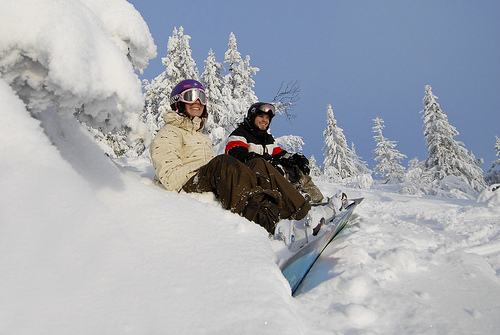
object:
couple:
[149, 80, 347, 253]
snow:
[1, 191, 497, 333]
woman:
[150, 79, 340, 251]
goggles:
[180, 88, 208, 106]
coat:
[150, 111, 215, 190]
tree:
[141, 26, 204, 131]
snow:
[0, 0, 159, 178]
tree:
[419, 83, 488, 190]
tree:
[320, 103, 374, 182]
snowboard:
[278, 197, 363, 296]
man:
[225, 103, 347, 213]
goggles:
[259, 103, 275, 115]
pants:
[176, 153, 311, 233]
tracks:
[344, 200, 500, 244]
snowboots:
[310, 197, 344, 219]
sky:
[126, 0, 498, 170]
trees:
[219, 31, 257, 136]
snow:
[144, 25, 498, 200]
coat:
[225, 124, 292, 162]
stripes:
[225, 134, 248, 154]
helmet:
[247, 102, 275, 123]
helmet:
[169, 79, 206, 117]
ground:
[1, 160, 494, 334]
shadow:
[295, 250, 343, 297]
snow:
[192, 171, 201, 191]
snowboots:
[274, 210, 327, 253]